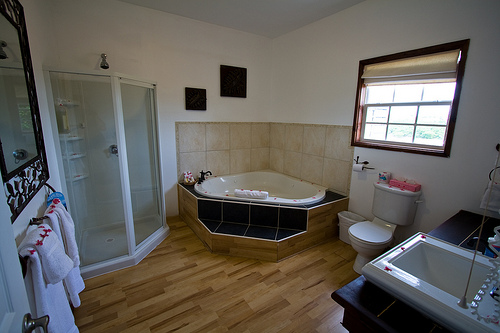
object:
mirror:
[0, 13, 40, 176]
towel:
[15, 224, 75, 285]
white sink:
[386, 238, 490, 306]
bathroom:
[0, 0, 499, 332]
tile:
[242, 225, 279, 242]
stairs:
[195, 219, 307, 263]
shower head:
[98, 52, 113, 70]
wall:
[266, 0, 499, 253]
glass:
[79, 181, 114, 213]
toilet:
[345, 181, 421, 276]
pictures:
[184, 87, 207, 111]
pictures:
[218, 65, 249, 100]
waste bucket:
[336, 210, 368, 245]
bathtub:
[176, 168, 346, 264]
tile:
[220, 202, 250, 228]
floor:
[67, 220, 357, 333]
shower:
[42, 73, 168, 282]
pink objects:
[387, 178, 422, 193]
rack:
[18, 182, 63, 278]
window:
[410, 124, 447, 147]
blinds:
[357, 49, 458, 79]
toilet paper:
[352, 162, 367, 173]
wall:
[0, 0, 268, 332]